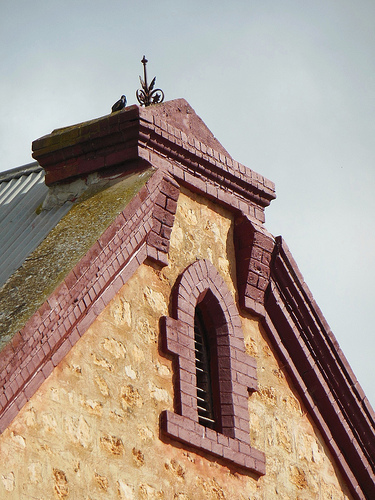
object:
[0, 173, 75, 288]
roofing material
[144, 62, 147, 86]
rod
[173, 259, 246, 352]
arch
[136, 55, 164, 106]
decoration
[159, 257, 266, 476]
frame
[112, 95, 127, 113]
bird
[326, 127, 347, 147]
ground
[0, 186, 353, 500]
wall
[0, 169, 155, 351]
moss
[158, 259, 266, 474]
window frame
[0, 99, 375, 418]
roof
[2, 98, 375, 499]
building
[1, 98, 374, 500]
front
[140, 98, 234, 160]
peak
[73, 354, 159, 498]
stone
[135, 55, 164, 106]
lightning rod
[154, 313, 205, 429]
trim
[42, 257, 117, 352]
trim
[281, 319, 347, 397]
trim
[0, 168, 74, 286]
aluminum slates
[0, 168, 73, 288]
metal siding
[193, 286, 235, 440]
window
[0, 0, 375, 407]
sky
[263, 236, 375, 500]
eave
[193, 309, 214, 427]
grid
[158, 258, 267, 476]
area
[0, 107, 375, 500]
brick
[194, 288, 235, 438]
window opening